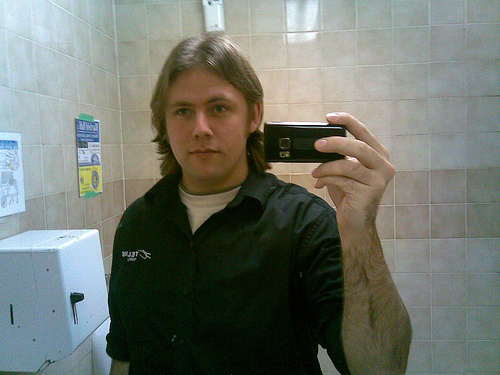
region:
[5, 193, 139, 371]
white metal paper towel dispenser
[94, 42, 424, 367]
man taking a selfie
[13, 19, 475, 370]
man taking a selfie in a bathroom mirror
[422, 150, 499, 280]
square tiles on bathroom walls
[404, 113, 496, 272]
square tiles two different colors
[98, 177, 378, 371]
black button down shirt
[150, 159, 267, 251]
white t-shirt under button down shirt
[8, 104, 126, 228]
papers taped to bathroom wall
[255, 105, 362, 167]
black cell phone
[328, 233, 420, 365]
lots of brown hair onmans arm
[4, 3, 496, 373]
two tone tile wall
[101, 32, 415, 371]
man standing in the bathroom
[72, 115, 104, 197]
paper hanging on the wall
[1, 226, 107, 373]
white paper towel dispenser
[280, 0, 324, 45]
reflection of light on tile wall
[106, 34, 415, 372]
man with a hairy arm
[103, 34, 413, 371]
man wearing a green shirt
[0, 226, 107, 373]
white paper towel dispenser with a black handle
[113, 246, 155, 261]
white writing on a green shirt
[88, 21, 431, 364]
person taking a selfie in the mirror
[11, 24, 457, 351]
person taking photograph in the bathroom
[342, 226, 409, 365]
lots of hair on man's arm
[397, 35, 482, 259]
square tiles on bathroom walls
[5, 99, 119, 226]
papers taped to bathroom walls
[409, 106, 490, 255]
square tiles covering bathroom walls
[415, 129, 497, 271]
two different color tiles on bathroom walls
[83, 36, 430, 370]
man taking a picture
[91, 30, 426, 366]
man taking a selfie in the bathroom mirror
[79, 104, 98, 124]
green tape used to tape paper to wall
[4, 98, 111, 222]
two papers taped to wall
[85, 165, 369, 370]
black buttoned down shirt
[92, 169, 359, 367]
black button down shirt with collar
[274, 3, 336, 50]
reflection of light on wall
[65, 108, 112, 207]
paper taped to wall with green tape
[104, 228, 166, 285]
white logo on black shirt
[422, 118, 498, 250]
stripe created with different color tiles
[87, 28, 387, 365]
man taking a selfie in the bathroom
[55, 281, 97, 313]
black handle of paper towel dispenser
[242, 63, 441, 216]
man holding cell phone with one hand